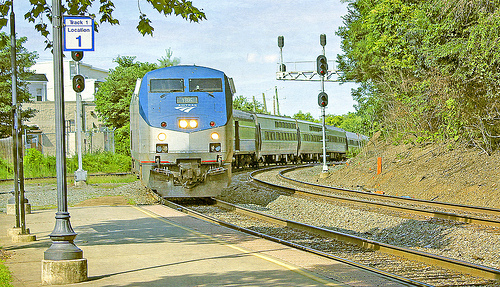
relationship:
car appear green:
[130, 65, 368, 197] [249, 119, 271, 145]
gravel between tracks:
[286, 198, 318, 222] [273, 173, 332, 245]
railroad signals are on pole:
[312, 51, 331, 109] [317, 117, 332, 172]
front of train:
[149, 79, 225, 168] [138, 77, 354, 176]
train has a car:
[138, 77, 354, 176] [130, 65, 368, 197]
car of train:
[130, 65, 368, 197] [138, 77, 354, 176]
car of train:
[326, 128, 347, 151] [138, 77, 354, 176]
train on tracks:
[138, 77, 354, 176] [273, 173, 332, 245]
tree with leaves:
[351, 12, 483, 76] [373, 4, 416, 39]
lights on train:
[176, 115, 204, 132] [138, 77, 354, 176]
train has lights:
[138, 77, 354, 176] [176, 115, 204, 132]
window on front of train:
[190, 80, 221, 93] [138, 77, 354, 176]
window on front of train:
[148, 78, 186, 92] [138, 77, 354, 176]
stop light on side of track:
[74, 74, 87, 107] [259, 165, 286, 185]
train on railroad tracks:
[138, 77, 354, 176] [259, 165, 286, 185]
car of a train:
[130, 65, 368, 197] [138, 77, 354, 176]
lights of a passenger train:
[176, 115, 204, 132] [234, 114, 257, 159]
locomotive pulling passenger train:
[129, 64, 239, 194] [234, 114, 257, 159]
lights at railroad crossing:
[176, 115, 204, 132] [297, 223, 360, 255]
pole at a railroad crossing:
[317, 117, 332, 172] [297, 223, 360, 255]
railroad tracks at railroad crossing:
[385, 242, 456, 286] [297, 223, 360, 255]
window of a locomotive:
[150, 78, 220, 93] [129, 64, 239, 194]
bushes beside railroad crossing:
[84, 152, 124, 173] [297, 223, 360, 255]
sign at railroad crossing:
[62, 17, 94, 52] [297, 223, 360, 255]